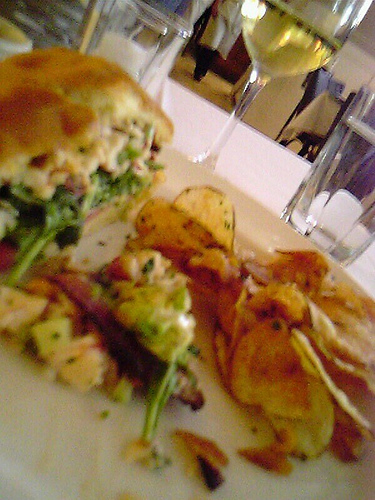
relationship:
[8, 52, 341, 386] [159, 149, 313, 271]
food on plate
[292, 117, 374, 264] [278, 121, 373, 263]
water in glass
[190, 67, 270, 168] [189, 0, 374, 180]
handle on glass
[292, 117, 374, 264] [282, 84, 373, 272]
water in glass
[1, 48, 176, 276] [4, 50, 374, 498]
sandwich on plate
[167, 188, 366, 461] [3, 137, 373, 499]
potato chips on plate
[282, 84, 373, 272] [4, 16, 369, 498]
glass on table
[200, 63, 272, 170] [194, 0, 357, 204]
stem on glass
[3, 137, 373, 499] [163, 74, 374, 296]
plate on table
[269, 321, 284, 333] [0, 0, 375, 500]
mark in food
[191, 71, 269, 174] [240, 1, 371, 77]
stand of glass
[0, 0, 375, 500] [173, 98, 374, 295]
food on table